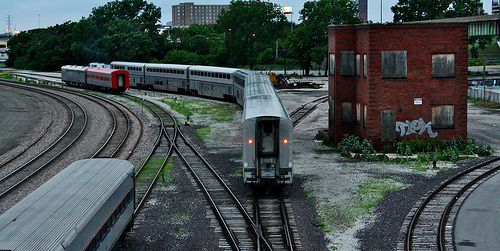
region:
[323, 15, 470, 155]
a red brick building is in between the tracks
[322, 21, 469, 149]
the building is boarded up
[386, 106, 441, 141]
graffiti is on the red brick building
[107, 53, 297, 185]
a train is on the tracks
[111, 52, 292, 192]
a double decker train in on the curve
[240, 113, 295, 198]
red lights are the back of the car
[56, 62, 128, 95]
two passenger cars are on the tracks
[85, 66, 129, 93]
a red passenger car is sitting on the tracks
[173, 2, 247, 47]
a tall building is in the backgound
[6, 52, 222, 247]
the train tracks are curving to the left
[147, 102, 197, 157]
the tracks are connected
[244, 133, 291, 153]
the lights are on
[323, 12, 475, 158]
the building is brick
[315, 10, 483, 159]
the building is small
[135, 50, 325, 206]
the train is gray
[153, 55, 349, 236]
the train is on tracks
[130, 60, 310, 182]
the train is long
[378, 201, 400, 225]
the gravel is black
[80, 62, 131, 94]
the train is red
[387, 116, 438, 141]
the building has graffiti on it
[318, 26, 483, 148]
red brick building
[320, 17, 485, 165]
two story red brick building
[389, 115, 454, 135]
graffiti on a red brick wall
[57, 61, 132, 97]
two train cars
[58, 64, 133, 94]
red train car beside silver train car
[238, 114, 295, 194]
dual lights on a train face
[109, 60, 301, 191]
short silver train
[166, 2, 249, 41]
tall building behind trees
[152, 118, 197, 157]
fork in the rail road tracks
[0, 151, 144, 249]
grey train car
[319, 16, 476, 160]
large red brick building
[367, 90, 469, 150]
graffiti painted on building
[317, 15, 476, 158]
large building with boarded windows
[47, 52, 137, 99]
two detached passenger cars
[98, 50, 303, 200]
small set of train cars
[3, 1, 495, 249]
train yard with passenger trains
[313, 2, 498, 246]
old abandoned train building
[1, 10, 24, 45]
very tall radio tower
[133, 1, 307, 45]
large brick building behind trees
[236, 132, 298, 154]
set of red train lights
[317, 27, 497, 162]
Two story brick building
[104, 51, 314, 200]
Silver passenger train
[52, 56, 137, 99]
Two cars on a side track not moving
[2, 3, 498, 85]
Green trees in the background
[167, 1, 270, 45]
Grey high rise building in the center background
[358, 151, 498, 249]
Side track on the right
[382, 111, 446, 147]
Graffitti on the brick building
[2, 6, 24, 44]
Power pole in the upper left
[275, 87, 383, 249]
Gravel area between the train and the building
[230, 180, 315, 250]
Visable part of the tracks that the silver train is on